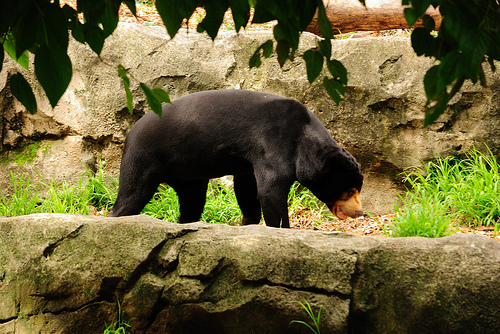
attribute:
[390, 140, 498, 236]
grass — tall 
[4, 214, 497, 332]
wall — rock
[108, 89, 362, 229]
bear — Small , black 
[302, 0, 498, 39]
tree — large , wood 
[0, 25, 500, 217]
wall — rock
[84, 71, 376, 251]
bear — black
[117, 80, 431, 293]
bear — black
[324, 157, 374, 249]
nose — brown 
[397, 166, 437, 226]
leaves — green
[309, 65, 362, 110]
leaf — green, small